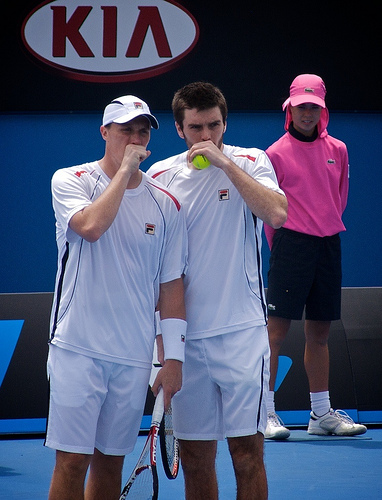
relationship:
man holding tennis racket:
[47, 89, 191, 498] [118, 388, 166, 500]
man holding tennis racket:
[146, 76, 291, 500] [161, 388, 184, 479]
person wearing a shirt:
[257, 70, 366, 442] [261, 130, 353, 247]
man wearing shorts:
[47, 89, 191, 498] [44, 342, 150, 463]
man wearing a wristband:
[47, 89, 191, 498] [159, 314, 191, 361]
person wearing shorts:
[257, 70, 366, 442] [265, 229, 346, 321]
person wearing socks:
[257, 70, 366, 442] [264, 387, 334, 414]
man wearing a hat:
[47, 89, 191, 498] [95, 94, 163, 129]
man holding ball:
[146, 76, 291, 500] [188, 151, 211, 170]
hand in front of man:
[121, 143, 151, 171] [47, 89, 191, 498]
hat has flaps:
[277, 74, 331, 141] [280, 103, 334, 137]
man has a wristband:
[47, 89, 191, 498] [159, 314, 191, 361]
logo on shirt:
[322, 158, 337, 165] [261, 130, 353, 247]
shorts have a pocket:
[44, 342, 150, 463] [49, 353, 92, 407]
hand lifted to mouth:
[121, 143, 151, 171] [122, 145, 147, 156]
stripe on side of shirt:
[50, 244, 72, 337] [46, 165, 190, 366]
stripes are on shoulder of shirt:
[64, 167, 185, 214] [46, 165, 190, 366]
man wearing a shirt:
[47, 89, 191, 498] [46, 165, 190, 366]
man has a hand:
[47, 89, 191, 498] [121, 143, 151, 171]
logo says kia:
[22, 2, 203, 83] [40, 1, 174, 57]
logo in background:
[22, 2, 203, 83] [5, 4, 369, 122]